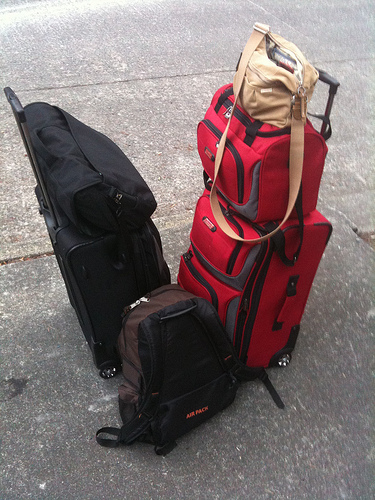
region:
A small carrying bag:
[211, 23, 317, 243]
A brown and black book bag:
[95, 283, 283, 461]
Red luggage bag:
[176, 186, 329, 368]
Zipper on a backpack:
[123, 297, 139, 315]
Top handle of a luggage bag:
[3, 86, 24, 119]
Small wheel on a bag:
[97, 362, 116, 379]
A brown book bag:
[94, 283, 285, 456]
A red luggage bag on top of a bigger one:
[196, 83, 329, 222]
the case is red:
[197, 84, 325, 218]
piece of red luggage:
[175, 191, 330, 365]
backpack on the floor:
[96, 283, 236, 455]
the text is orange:
[186, 405, 207, 418]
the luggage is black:
[3, 86, 172, 377]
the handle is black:
[4, 87, 24, 123]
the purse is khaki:
[211, 23, 318, 241]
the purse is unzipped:
[265, 35, 303, 82]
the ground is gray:
[1, 0, 373, 499]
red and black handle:
[272, 275, 297, 330]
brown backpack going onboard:
[93, 281, 244, 455]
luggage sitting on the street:
[2, 19, 350, 492]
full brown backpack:
[95, 278, 247, 453]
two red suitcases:
[181, 47, 341, 372]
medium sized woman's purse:
[209, 19, 319, 249]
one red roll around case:
[177, 185, 337, 384]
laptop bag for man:
[19, 99, 160, 232]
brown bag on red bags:
[232, 11, 317, 135]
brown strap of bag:
[210, 127, 318, 242]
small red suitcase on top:
[187, 116, 331, 213]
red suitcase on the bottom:
[183, 199, 331, 381]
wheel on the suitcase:
[271, 345, 295, 374]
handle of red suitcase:
[277, 271, 295, 339]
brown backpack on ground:
[100, 288, 246, 442]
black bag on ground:
[23, 95, 166, 224]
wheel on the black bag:
[96, 363, 119, 382]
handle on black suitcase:
[0, 77, 54, 206]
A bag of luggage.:
[181, 193, 321, 371]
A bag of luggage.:
[199, 94, 352, 201]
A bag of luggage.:
[234, 40, 312, 131]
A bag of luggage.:
[104, 278, 235, 455]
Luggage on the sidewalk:
[1, 22, 337, 455]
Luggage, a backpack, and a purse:
[4, 21, 340, 454]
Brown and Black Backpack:
[96, 284, 286, 457]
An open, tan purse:
[210, 17, 320, 240]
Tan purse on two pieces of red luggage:
[178, 18, 340, 367]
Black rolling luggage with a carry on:
[3, 90, 172, 376]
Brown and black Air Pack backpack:
[97, 284, 287, 455]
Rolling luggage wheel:
[274, 351, 292, 367]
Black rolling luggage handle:
[3, 87, 68, 232]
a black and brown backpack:
[94, 282, 247, 458]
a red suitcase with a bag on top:
[177, 67, 342, 369]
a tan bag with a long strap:
[207, 21, 321, 244]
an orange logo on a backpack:
[183, 404, 210, 420]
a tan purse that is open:
[209, 20, 320, 243]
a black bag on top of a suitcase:
[19, 98, 158, 237]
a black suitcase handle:
[307, 67, 341, 141]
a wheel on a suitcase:
[275, 351, 292, 370]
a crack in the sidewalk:
[0, 55, 373, 95]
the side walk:
[141, 94, 173, 134]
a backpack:
[121, 291, 234, 441]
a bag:
[44, 108, 129, 202]